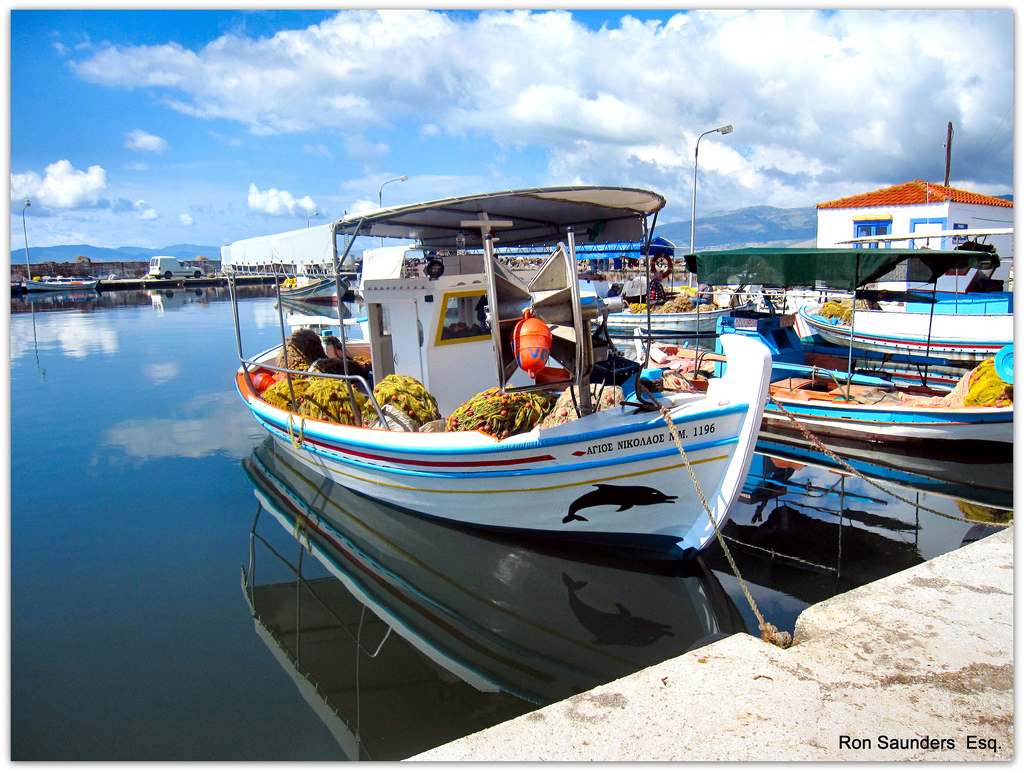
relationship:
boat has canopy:
[219, 186, 769, 550] [312, 177, 670, 282]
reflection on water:
[195, 424, 686, 722] [54, 361, 685, 734]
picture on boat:
[559, 462, 692, 533] [214, 158, 768, 551]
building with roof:
[789, 168, 1014, 249] [809, 165, 1009, 211]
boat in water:
[219, 186, 769, 550] [22, 282, 766, 657]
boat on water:
[740, 335, 1013, 498] [85, 289, 945, 591]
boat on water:
[174, 166, 792, 571] [47, 297, 326, 694]